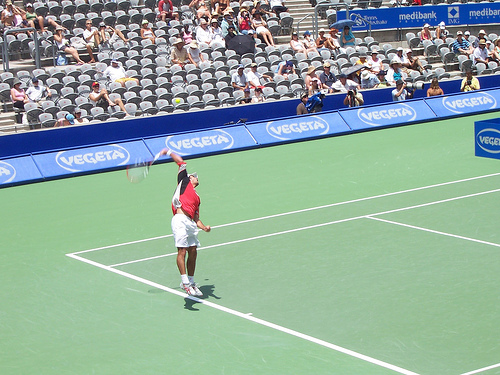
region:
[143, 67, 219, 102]
empty chairs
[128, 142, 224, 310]
tennis player hitting ball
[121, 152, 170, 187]
tennis racket in motion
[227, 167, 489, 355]
portion of tennis field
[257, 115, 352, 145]
Vegeta advertisement sign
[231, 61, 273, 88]
spectators watching tennis match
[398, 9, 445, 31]
Medibank advertisement on sign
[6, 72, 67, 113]
couple with hats and glasses on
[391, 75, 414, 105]
man taking pictures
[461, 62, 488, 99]
man with yellow shirt holding camera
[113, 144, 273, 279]
player on a tennis court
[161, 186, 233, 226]
red shirt on man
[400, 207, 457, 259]
white line on court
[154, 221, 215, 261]
white shorts on man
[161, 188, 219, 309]
red and white shirt on man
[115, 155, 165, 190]
racket of the man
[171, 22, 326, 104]
fans in the audience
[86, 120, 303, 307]
man swinging a racket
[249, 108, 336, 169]
advertisement on the left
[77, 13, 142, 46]
people watching the match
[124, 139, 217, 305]
tennis player swings his racket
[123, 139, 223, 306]
tennis player jumps up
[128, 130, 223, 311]
tennis player is wearing a red, white and black shirt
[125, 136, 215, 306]
tennis player is wearing white shorts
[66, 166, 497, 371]
the lines of a tennis court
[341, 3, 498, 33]
names of sponsors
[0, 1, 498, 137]
audience watching tennis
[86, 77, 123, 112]
a man wearing a red cap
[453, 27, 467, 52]
a wearing a striped shirt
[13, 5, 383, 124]
several empty seats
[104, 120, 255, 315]
tennis player playing tennis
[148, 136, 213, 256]
tennis player wearing white shorts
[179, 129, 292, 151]
white letters on blue background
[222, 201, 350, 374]
chalk outline on tennis court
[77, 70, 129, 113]
person in red cap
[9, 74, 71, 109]
people sitting in seats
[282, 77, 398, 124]
cameramen standing behind wall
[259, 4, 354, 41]
stairs and railing to seating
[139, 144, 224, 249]
man wearing red, white, and black shirt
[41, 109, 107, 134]
person wearing blue hat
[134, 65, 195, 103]
empty seats at a tennis game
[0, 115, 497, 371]
a green tennis court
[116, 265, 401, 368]
a white line on a tennis court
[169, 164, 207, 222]
a red, black, and white shirt on a tennis player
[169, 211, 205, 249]
white shorts on a tennis player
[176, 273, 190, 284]
white socks on a tennis player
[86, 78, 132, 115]
a spectator with legs draped over the chair in front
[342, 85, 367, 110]
a camera man filming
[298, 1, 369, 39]
a metal rail at the stairs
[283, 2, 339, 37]
concrete stairs